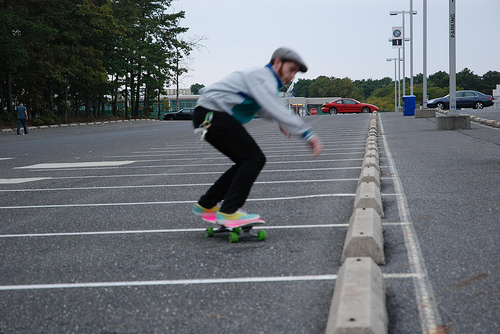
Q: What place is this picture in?
A: It is at the parking lot.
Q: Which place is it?
A: It is a parking lot.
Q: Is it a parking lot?
A: Yes, it is a parking lot.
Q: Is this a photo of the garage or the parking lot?
A: It is showing the parking lot.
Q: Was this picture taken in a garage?
A: No, the picture was taken in a parking lot.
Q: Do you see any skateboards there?
A: Yes, there is a skateboard.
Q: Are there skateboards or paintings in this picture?
A: Yes, there is a skateboard.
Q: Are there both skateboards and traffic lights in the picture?
A: No, there is a skateboard but no traffic lights.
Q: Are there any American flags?
A: No, there are no American flags.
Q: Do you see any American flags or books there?
A: No, there are no American flags or books.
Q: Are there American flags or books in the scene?
A: No, there are no American flags or books.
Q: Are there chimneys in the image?
A: No, there are no chimneys.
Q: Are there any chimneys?
A: No, there are no chimneys.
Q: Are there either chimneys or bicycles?
A: No, there are no chimneys or bicycles.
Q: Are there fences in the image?
A: No, there are no fences.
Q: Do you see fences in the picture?
A: No, there are no fences.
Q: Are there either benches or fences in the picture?
A: No, there are no fences or benches.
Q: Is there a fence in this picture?
A: No, there are no fences.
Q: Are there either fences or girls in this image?
A: No, there are no fences or girls.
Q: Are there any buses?
A: No, there are no buses.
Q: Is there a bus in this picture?
A: No, there are no buses.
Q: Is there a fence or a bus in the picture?
A: No, there are no buses or fences.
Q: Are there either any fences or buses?
A: No, there are no buses or fences.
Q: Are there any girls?
A: No, there are no girls.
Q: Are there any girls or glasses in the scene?
A: No, there are no girls or glasses.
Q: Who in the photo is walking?
A: The man is walking.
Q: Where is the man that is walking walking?
A: The man is walking in the parking lot.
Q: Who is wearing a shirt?
A: The man is wearing a shirt.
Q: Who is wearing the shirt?
A: The man is wearing a shirt.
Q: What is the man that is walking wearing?
A: The man is wearing a shirt.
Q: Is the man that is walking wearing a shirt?
A: Yes, the man is wearing a shirt.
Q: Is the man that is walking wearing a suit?
A: No, the man is wearing a shirt.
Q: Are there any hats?
A: Yes, there is a hat.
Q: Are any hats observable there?
A: Yes, there is a hat.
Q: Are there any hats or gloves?
A: Yes, there is a hat.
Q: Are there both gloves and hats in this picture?
A: No, there is a hat but no gloves.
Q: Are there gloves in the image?
A: No, there are no gloves.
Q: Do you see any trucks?
A: No, there are no trucks.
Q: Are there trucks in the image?
A: No, there are no trucks.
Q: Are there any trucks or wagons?
A: No, there are no trucks or wagons.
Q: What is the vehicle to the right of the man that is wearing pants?
A: The vehicle is a car.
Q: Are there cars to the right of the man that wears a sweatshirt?
A: Yes, there is a car to the right of the man.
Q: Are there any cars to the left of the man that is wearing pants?
A: No, the car is to the right of the man.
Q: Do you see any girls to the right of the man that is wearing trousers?
A: No, there is a car to the right of the man.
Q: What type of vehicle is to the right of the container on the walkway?
A: The vehicle is a car.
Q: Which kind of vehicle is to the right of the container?
A: The vehicle is a car.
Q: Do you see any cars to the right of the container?
A: Yes, there is a car to the right of the container.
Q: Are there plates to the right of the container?
A: No, there is a car to the right of the container.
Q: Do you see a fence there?
A: No, there are no fences.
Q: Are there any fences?
A: No, there are no fences.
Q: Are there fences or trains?
A: No, there are no fences or trains.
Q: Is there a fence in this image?
A: No, there are no fences.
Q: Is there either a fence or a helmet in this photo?
A: No, there are no fences or helmets.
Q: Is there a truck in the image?
A: No, there are no trucks.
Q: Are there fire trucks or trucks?
A: No, there are no trucks or fire trucks.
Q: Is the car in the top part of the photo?
A: Yes, the car is in the top of the image.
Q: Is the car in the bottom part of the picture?
A: No, the car is in the top of the image.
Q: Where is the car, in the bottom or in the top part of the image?
A: The car is in the top of the image.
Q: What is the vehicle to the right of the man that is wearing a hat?
A: The vehicle is a car.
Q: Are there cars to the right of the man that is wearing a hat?
A: Yes, there is a car to the right of the man.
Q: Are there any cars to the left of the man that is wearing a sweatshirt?
A: No, the car is to the right of the man.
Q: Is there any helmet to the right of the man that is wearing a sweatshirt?
A: No, there is a car to the right of the man.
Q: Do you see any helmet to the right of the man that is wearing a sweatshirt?
A: No, there is a car to the right of the man.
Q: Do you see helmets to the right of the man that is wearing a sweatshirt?
A: No, there is a car to the right of the man.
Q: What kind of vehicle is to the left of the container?
A: The vehicle is a car.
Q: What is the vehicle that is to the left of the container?
A: The vehicle is a car.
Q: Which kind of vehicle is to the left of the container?
A: The vehicle is a car.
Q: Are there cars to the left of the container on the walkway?
A: Yes, there is a car to the left of the container.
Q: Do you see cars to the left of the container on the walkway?
A: Yes, there is a car to the left of the container.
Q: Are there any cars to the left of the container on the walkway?
A: Yes, there is a car to the left of the container.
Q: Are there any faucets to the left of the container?
A: No, there is a car to the left of the container.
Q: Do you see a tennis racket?
A: No, there are no rackets.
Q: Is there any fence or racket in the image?
A: No, there are no rackets or fences.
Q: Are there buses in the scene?
A: No, there are no buses.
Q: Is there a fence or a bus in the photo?
A: No, there are no buses or fences.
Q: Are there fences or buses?
A: No, there are no buses or fences.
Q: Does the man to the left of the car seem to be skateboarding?
A: Yes, the man is skateboarding.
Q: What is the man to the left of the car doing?
A: The man is skateboarding.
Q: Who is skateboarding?
A: The man is skateboarding.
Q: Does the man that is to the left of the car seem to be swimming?
A: No, the man is skateboarding.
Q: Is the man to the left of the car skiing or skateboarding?
A: The man is skateboarding.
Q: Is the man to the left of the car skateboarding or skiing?
A: The man is skateboarding.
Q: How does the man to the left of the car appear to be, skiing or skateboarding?
A: The man is skateboarding.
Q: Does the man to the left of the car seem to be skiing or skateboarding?
A: The man is skateboarding.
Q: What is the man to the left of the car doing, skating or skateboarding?
A: The man is skateboarding.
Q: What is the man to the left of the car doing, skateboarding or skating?
A: The man is skateboarding.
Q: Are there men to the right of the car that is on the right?
A: No, the man is to the left of the car.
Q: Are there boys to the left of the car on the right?
A: No, there is a man to the left of the car.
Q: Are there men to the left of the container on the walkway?
A: Yes, there is a man to the left of the container.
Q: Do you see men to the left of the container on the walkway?
A: Yes, there is a man to the left of the container.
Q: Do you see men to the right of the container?
A: No, the man is to the left of the container.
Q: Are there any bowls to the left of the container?
A: No, there is a man to the left of the container.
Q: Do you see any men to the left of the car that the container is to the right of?
A: Yes, there is a man to the left of the car.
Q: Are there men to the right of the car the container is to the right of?
A: No, the man is to the left of the car.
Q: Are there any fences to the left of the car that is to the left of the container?
A: No, there is a man to the left of the car.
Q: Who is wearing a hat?
A: The man is wearing a hat.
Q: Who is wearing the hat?
A: The man is wearing a hat.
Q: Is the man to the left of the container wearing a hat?
A: Yes, the man is wearing a hat.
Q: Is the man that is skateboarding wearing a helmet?
A: No, the man is wearing a hat.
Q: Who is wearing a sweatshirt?
A: The man is wearing a sweatshirt.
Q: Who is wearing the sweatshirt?
A: The man is wearing a sweatshirt.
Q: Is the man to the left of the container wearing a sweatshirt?
A: Yes, the man is wearing a sweatshirt.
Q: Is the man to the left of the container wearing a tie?
A: No, the man is wearing a sweatshirt.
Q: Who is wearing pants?
A: The man is wearing pants.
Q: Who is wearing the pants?
A: The man is wearing pants.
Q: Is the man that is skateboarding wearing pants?
A: Yes, the man is wearing pants.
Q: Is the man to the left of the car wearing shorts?
A: No, the man is wearing pants.